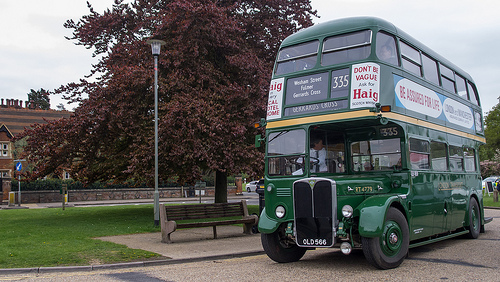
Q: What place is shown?
A: It is a street.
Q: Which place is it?
A: It is a street.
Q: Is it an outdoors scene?
A: Yes, it is outdoors.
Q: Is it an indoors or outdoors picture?
A: It is outdoors.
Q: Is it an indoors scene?
A: No, it is outdoors.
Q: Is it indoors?
A: No, it is outdoors.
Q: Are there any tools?
A: No, there are no tools.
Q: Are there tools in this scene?
A: No, there are no tools.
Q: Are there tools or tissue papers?
A: No, there are no tools or tissue papers.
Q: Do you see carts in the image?
A: No, there are no carts.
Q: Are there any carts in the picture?
A: No, there are no carts.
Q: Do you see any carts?
A: No, there are no carts.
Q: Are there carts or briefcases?
A: No, there are no carts or briefcases.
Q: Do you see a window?
A: Yes, there are windows.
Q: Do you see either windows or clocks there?
A: Yes, there are windows.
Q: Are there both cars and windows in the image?
A: Yes, there are both windows and a car.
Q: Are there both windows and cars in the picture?
A: Yes, there are both windows and a car.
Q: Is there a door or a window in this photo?
A: Yes, there are windows.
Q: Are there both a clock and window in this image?
A: No, there are windows but no clocks.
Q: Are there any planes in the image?
A: No, there are no planes.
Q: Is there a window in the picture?
A: Yes, there are windows.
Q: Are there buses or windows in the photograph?
A: Yes, there are windows.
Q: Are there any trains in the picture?
A: No, there are no trains.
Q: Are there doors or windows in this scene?
A: Yes, there are windows.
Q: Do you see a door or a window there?
A: Yes, there are windows.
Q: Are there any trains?
A: No, there are no trains.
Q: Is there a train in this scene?
A: No, there are no trains.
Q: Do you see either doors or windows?
A: Yes, there are windows.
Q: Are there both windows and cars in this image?
A: Yes, there are both windows and a car.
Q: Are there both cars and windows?
A: Yes, there are both windows and a car.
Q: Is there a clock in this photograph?
A: No, there are no clocks.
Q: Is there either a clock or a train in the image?
A: No, there are no clocks or trains.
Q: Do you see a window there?
A: Yes, there are windows.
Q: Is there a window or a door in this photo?
A: Yes, there are windows.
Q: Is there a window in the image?
A: Yes, there are windows.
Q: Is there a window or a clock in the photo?
A: Yes, there are windows.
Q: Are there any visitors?
A: No, there are no visitors.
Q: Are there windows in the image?
A: Yes, there are windows.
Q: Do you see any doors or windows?
A: Yes, there are windows.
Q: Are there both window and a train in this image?
A: No, there are windows but no trains.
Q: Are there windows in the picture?
A: Yes, there are windows.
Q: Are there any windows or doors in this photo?
A: Yes, there are windows.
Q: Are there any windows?
A: Yes, there are windows.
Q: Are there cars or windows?
A: Yes, there are windows.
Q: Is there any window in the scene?
A: Yes, there are windows.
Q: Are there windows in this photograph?
A: Yes, there are windows.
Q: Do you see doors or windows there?
A: Yes, there are windows.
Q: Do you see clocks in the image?
A: No, there are no clocks.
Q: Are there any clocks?
A: No, there are no clocks.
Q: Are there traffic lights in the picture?
A: No, there are no traffic lights.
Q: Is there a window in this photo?
A: Yes, there are windows.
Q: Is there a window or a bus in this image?
A: Yes, there are windows.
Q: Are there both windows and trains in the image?
A: No, there are windows but no trains.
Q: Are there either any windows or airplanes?
A: Yes, there are windows.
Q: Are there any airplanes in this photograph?
A: No, there are no airplanes.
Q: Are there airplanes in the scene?
A: No, there are no airplanes.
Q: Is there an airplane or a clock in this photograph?
A: No, there are no airplanes or clocks.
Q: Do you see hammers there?
A: No, there are no hammers.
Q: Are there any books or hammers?
A: No, there are no hammers or books.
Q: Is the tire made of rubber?
A: Yes, the tire is made of rubber.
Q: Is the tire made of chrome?
A: No, the tire is made of rubber.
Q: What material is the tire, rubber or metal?
A: The tire is made of rubber.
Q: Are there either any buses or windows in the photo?
A: Yes, there are windows.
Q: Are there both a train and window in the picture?
A: No, there are windows but no trains.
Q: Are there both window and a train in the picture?
A: No, there are windows but no trains.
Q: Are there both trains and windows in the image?
A: No, there are windows but no trains.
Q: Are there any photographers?
A: No, there are no photographers.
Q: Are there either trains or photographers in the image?
A: No, there are no photographers or trains.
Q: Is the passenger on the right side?
A: Yes, the passenger is on the right of the image.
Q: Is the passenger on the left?
A: No, the passenger is on the right of the image.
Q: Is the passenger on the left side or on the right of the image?
A: The passenger is on the right of the image.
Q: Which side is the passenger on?
A: The passenger is on the right of the image.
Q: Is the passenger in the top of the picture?
A: Yes, the passenger is in the top of the image.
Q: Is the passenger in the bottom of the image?
A: No, the passenger is in the top of the image.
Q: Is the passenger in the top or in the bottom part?
A: The passenger is in the top of the image.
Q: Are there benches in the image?
A: Yes, there is a bench.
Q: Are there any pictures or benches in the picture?
A: Yes, there is a bench.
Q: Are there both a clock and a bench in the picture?
A: No, there is a bench but no clocks.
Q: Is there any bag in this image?
A: No, there are no bags.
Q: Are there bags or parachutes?
A: No, there are no bags or parachutes.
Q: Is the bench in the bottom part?
A: Yes, the bench is in the bottom of the image.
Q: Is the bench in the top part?
A: No, the bench is in the bottom of the image.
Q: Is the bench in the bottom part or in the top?
A: The bench is in the bottom of the image.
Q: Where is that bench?
A: The bench is on the sidewalk.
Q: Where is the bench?
A: The bench is on the sidewalk.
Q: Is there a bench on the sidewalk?
A: Yes, there is a bench on the sidewalk.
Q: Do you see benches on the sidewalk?
A: Yes, there is a bench on the sidewalk.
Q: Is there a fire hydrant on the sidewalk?
A: No, there is a bench on the sidewalk.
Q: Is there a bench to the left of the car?
A: Yes, there is a bench to the left of the car.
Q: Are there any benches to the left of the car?
A: Yes, there is a bench to the left of the car.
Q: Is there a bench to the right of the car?
A: No, the bench is to the left of the car.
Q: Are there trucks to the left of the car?
A: No, there is a bench to the left of the car.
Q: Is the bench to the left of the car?
A: Yes, the bench is to the left of the car.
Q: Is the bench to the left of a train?
A: No, the bench is to the left of the car.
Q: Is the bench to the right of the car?
A: No, the bench is to the left of the car.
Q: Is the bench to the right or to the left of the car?
A: The bench is to the left of the car.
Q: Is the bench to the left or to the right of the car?
A: The bench is to the left of the car.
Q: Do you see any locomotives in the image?
A: No, there are no locomotives.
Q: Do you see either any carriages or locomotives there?
A: No, there are no locomotives or carriages.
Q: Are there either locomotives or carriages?
A: No, there are no locomotives or carriages.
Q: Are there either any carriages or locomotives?
A: No, there are no locomotives or carriages.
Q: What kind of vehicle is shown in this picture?
A: The vehicle is a car.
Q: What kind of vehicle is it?
A: The vehicle is a car.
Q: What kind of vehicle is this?
A: This is a car.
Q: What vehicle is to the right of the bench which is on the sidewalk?
A: The vehicle is a car.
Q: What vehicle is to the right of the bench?
A: The vehicle is a car.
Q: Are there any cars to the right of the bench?
A: Yes, there is a car to the right of the bench.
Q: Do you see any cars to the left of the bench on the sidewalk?
A: No, the car is to the right of the bench.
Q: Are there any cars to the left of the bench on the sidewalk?
A: No, the car is to the right of the bench.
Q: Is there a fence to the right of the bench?
A: No, there is a car to the right of the bench.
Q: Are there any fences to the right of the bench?
A: No, there is a car to the right of the bench.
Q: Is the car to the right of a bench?
A: Yes, the car is to the right of a bench.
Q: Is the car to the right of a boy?
A: No, the car is to the right of a bench.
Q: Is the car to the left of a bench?
A: No, the car is to the right of a bench.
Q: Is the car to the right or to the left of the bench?
A: The car is to the right of the bench.